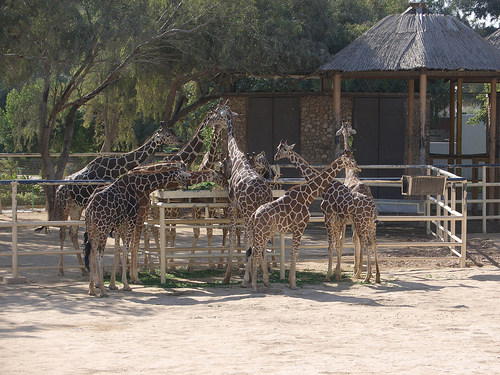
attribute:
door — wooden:
[353, 89, 411, 185]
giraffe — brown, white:
[241, 149, 358, 292]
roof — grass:
[314, 7, 497, 78]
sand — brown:
[205, 290, 486, 368]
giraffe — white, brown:
[54, 113, 219, 300]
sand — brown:
[15, 289, 217, 374]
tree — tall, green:
[4, 5, 211, 217]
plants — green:
[69, 54, 231, 165]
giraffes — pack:
[43, 37, 413, 324]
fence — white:
[421, 167, 473, 264]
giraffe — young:
[272, 140, 383, 285]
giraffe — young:
[248, 152, 363, 272]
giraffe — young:
[208, 105, 277, 214]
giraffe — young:
[92, 162, 193, 280]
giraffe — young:
[64, 126, 176, 225]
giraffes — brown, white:
[40, 114, 173, 277]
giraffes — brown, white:
[85, 160, 192, 298]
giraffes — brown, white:
[126, 84, 240, 271]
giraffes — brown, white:
[222, 113, 276, 283]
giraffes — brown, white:
[247, 150, 362, 285]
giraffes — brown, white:
[274, 133, 391, 285]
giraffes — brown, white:
[337, 121, 385, 278]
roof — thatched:
[311, 2, 498, 80]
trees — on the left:
[2, 3, 499, 209]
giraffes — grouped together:
[30, 87, 395, 299]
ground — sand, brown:
[34, 286, 166, 373]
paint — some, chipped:
[1, 157, 139, 189]